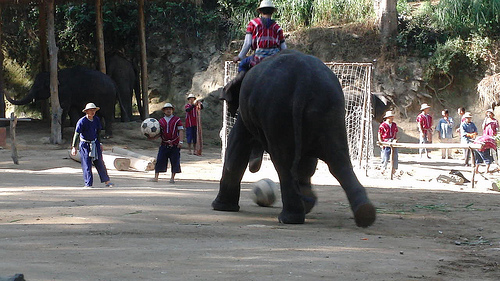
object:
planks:
[384, 142, 483, 150]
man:
[230, 0, 289, 73]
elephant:
[207, 49, 377, 228]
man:
[144, 101, 186, 185]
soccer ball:
[139, 116, 161, 140]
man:
[68, 101, 116, 188]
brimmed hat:
[80, 102, 103, 114]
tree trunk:
[375, 1, 400, 47]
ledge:
[227, 0, 497, 66]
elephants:
[0, 64, 119, 139]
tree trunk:
[46, 1, 63, 145]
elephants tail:
[289, 70, 310, 199]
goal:
[218, 61, 375, 178]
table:
[374, 141, 499, 189]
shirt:
[241, 16, 286, 51]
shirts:
[152, 115, 185, 148]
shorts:
[153, 140, 181, 173]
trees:
[0, 0, 258, 144]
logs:
[66, 149, 132, 170]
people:
[377, 110, 400, 169]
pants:
[80, 139, 109, 187]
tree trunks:
[137, 1, 151, 122]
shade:
[0, 62, 74, 144]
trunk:
[5, 82, 41, 107]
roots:
[365, 0, 452, 119]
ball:
[249, 178, 277, 206]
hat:
[254, 0, 280, 11]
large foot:
[211, 195, 242, 212]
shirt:
[72, 116, 103, 143]